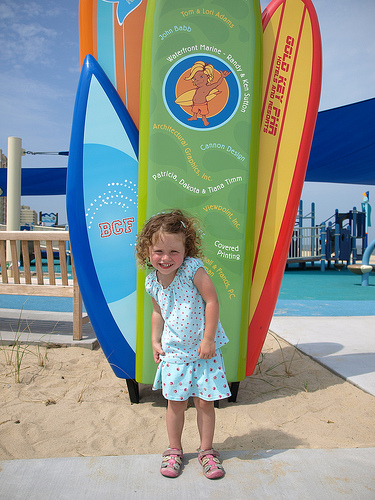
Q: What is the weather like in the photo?
A: It is partly cloudy.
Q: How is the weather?
A: It is partly cloudy.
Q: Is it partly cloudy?
A: Yes, it is partly cloudy.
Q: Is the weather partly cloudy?
A: Yes, it is partly cloudy.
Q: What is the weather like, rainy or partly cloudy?
A: It is partly cloudy.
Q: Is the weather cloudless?
A: No, it is partly cloudy.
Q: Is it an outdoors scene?
A: Yes, it is outdoors.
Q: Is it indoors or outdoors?
A: It is outdoors.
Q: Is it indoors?
A: No, it is outdoors.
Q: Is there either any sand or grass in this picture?
A: Yes, there is sand.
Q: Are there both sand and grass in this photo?
A: Yes, there are both sand and grass.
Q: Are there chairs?
A: No, there are no chairs.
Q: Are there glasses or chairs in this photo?
A: No, there are no chairs or glasses.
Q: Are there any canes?
A: No, there are no canes.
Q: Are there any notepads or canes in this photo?
A: No, there are no canes or notepads.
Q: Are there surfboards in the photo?
A: Yes, there is a surfboard.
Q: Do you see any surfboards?
A: Yes, there is a surfboard.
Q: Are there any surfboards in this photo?
A: Yes, there is a surfboard.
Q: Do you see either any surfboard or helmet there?
A: Yes, there is a surfboard.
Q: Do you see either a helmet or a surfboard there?
A: Yes, there is a surfboard.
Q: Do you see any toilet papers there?
A: No, there are no toilet papers.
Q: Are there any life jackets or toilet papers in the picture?
A: No, there are no toilet papers or life jackets.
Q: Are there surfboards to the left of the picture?
A: Yes, there is a surfboard to the left of the picture.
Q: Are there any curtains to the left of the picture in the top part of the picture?
A: No, there is a surfboard to the left of the picture.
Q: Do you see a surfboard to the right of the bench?
A: Yes, there is a surfboard to the right of the bench.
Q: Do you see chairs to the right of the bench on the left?
A: No, there is a surfboard to the right of the bench.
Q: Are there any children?
A: Yes, there is a child.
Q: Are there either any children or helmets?
A: Yes, there is a child.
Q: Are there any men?
A: No, there are no men.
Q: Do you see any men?
A: No, there are no men.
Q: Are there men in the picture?
A: No, there are no men.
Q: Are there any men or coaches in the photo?
A: No, there are no men or coaches.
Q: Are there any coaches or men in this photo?
A: No, there are no men or coaches.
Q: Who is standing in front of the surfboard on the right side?
A: The kid is standing in front of the surf board.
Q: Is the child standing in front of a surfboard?
A: Yes, the child is standing in front of a surfboard.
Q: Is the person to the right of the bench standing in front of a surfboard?
A: Yes, the child is standing in front of a surfboard.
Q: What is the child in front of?
A: The child is in front of the surfboard.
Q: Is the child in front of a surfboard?
A: Yes, the child is in front of a surfboard.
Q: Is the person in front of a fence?
A: No, the child is in front of a surfboard.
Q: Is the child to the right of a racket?
A: No, the child is to the right of the surfboard.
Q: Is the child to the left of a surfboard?
A: No, the child is to the right of a surfboard.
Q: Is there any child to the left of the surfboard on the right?
A: Yes, there is a child to the left of the surf board.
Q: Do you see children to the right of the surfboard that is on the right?
A: No, the child is to the left of the surfboard.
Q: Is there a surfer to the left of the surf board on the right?
A: No, there is a child to the left of the surfboard.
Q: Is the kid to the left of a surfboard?
A: Yes, the kid is to the left of a surfboard.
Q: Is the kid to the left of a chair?
A: No, the kid is to the left of a surfboard.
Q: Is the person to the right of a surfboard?
A: No, the child is to the left of a surfboard.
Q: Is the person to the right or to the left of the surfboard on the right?
A: The child is to the left of the surfboard.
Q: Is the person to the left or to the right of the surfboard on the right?
A: The child is to the left of the surfboard.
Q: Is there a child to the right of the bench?
A: Yes, there is a child to the right of the bench.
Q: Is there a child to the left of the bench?
A: No, the child is to the right of the bench.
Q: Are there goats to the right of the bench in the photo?
A: No, there is a child to the right of the bench.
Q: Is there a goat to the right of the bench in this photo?
A: No, there is a child to the right of the bench.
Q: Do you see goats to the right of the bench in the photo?
A: No, there is a child to the right of the bench.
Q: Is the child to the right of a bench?
A: Yes, the child is to the right of a bench.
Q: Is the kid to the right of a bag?
A: No, the kid is to the right of a bench.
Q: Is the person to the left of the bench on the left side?
A: No, the kid is to the right of the bench.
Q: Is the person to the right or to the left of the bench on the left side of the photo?
A: The kid is to the right of the bench.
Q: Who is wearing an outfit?
A: The kid is wearing an outfit.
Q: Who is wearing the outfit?
A: The kid is wearing an outfit.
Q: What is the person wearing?
A: The kid is wearing an outfit.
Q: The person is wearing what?
A: The kid is wearing an outfit.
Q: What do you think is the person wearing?
A: The kid is wearing an outfit.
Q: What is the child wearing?
A: The kid is wearing an outfit.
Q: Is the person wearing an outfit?
A: Yes, the child is wearing an outfit.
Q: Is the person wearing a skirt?
A: No, the kid is wearing an outfit.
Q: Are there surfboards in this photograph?
A: Yes, there is a surfboard.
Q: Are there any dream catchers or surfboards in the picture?
A: Yes, there is a surfboard.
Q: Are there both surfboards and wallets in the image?
A: No, there is a surfboard but no wallets.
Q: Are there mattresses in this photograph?
A: No, there are no mattresses.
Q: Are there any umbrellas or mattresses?
A: No, there are no mattresses or umbrellas.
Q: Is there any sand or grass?
A: Yes, there is sand.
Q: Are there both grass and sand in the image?
A: Yes, there are both sand and grass.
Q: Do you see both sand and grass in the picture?
A: Yes, there are both sand and grass.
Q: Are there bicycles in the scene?
A: No, there are no bicycles.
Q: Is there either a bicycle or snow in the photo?
A: No, there are no bicycles or snow.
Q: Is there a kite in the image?
A: No, there are no kites.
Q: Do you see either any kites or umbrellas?
A: No, there are no kites or umbrellas.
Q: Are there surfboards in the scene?
A: Yes, there is a surfboard.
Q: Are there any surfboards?
A: Yes, there is a surfboard.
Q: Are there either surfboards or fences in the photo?
A: Yes, there is a surfboard.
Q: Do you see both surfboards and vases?
A: No, there is a surfboard but no vases.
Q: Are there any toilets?
A: No, there are no toilets.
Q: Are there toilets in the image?
A: No, there are no toilets.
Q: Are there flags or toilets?
A: No, there are no toilets or flags.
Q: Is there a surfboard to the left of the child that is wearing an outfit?
A: Yes, there is a surfboard to the left of the child.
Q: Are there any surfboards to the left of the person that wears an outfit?
A: Yes, there is a surfboard to the left of the child.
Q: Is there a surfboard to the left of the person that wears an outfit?
A: Yes, there is a surfboard to the left of the child.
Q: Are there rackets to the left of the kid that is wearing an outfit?
A: No, there is a surfboard to the left of the child.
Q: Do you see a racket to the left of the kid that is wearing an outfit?
A: No, there is a surfboard to the left of the child.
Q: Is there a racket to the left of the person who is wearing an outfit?
A: No, there is a surfboard to the left of the child.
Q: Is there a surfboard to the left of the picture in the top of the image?
A: Yes, there is a surfboard to the left of the picture.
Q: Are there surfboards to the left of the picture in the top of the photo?
A: Yes, there is a surfboard to the left of the picture.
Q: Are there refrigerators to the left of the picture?
A: No, there is a surfboard to the left of the picture.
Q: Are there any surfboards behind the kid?
A: Yes, there is a surfboard behind the kid.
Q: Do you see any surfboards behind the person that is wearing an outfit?
A: Yes, there is a surfboard behind the kid.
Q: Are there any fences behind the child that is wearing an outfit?
A: No, there is a surfboard behind the child.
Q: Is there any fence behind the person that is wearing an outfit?
A: No, there is a surfboard behind the child.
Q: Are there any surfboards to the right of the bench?
A: Yes, there is a surfboard to the right of the bench.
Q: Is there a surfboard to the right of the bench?
A: Yes, there is a surfboard to the right of the bench.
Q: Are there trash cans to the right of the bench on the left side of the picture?
A: No, there is a surfboard to the right of the bench.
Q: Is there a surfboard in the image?
A: Yes, there is a surfboard.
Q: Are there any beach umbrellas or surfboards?
A: Yes, there is a surfboard.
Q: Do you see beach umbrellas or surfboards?
A: Yes, there is a surfboard.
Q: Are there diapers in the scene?
A: No, there are no diapers.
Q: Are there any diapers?
A: No, there are no diapers.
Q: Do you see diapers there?
A: No, there are no diapers.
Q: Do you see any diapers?
A: No, there are no diapers.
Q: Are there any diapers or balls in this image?
A: No, there are no diapers or balls.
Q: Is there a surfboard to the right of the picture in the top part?
A: Yes, there is a surfboard to the right of the picture.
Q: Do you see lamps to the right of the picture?
A: No, there is a surfboard to the right of the picture.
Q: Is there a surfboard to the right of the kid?
A: Yes, there is a surfboard to the right of the kid.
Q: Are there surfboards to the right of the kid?
A: Yes, there is a surfboard to the right of the kid.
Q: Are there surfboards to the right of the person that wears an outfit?
A: Yes, there is a surfboard to the right of the kid.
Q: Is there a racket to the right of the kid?
A: No, there is a surfboard to the right of the kid.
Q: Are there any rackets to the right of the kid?
A: No, there is a surfboard to the right of the kid.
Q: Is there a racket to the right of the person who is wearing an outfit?
A: No, there is a surfboard to the right of the kid.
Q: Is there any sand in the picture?
A: Yes, there is sand.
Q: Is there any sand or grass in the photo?
A: Yes, there is sand.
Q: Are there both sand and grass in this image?
A: Yes, there are both sand and grass.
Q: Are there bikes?
A: No, there are no bikes.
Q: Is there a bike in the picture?
A: No, there are no bikes.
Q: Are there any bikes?
A: No, there are no bikes.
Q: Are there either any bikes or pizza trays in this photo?
A: No, there are no bikes or pizza trays.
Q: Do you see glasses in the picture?
A: No, there are no glasses.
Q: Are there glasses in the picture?
A: No, there are no glasses.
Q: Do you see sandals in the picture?
A: Yes, there are sandals.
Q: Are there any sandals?
A: Yes, there are sandals.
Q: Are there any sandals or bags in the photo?
A: Yes, there are sandals.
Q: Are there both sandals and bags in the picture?
A: No, there are sandals but no bags.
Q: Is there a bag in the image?
A: No, there are no bags.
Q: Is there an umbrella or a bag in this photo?
A: No, there are no bags or umbrellas.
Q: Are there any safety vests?
A: No, there are no safety vests.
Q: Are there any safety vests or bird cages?
A: No, there are no safety vests or bird cages.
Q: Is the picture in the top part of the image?
A: Yes, the picture is in the top of the image.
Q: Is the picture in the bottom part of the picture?
A: No, the picture is in the top of the image.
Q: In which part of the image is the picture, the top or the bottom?
A: The picture is in the top of the image.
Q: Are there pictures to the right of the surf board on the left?
A: Yes, there is a picture to the right of the surf board.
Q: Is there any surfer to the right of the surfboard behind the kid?
A: No, there is a picture to the right of the surfboard.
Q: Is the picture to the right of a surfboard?
A: Yes, the picture is to the right of a surfboard.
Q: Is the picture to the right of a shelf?
A: No, the picture is to the right of a surfboard.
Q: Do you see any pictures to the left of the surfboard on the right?
A: Yes, there is a picture to the left of the surfboard.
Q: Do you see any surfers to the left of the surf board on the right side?
A: No, there is a picture to the left of the surfboard.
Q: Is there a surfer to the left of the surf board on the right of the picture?
A: No, there is a picture to the left of the surfboard.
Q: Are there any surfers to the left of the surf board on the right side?
A: No, there is a picture to the left of the surfboard.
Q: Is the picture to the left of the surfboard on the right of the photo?
A: Yes, the picture is to the left of the surfboard.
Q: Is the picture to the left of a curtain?
A: No, the picture is to the left of the surfboard.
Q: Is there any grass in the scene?
A: Yes, there is grass.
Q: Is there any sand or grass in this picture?
A: Yes, there is grass.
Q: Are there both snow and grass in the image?
A: No, there is grass but no snow.